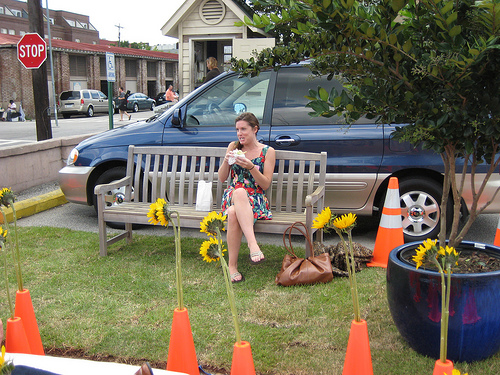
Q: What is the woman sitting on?
A: A bench.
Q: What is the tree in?
A: Blue flower pot.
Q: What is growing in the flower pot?
A: A tree.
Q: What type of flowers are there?
A: Sunflowers.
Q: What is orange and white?
A: Traffic cones.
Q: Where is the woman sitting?
A: On a bench.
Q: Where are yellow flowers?
A: In traffic cones.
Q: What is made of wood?
A: The bench.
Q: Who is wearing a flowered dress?
A: A woman.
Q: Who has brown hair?
A: A woman.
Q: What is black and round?
A: Tires.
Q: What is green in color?
A: Grass.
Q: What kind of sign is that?
A: It is a stop sign.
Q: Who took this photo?
A: Jackson Mingus.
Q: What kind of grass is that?
A: It is green grass.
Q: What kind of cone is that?
A: It's an orange cone.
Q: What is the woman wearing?
A: A dress.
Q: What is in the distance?
A: A blue van.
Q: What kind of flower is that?
A: It's a sunflower.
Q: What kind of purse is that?
A: It's a brown purse.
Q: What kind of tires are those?
A: They are black tires.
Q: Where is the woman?
A: On the bench.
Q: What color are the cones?
A: Orange.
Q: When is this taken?
A: During the day.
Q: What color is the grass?
A: Green.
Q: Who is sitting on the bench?
A: A woman.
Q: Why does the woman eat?
A: She is hungry.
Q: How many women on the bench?
A: One.